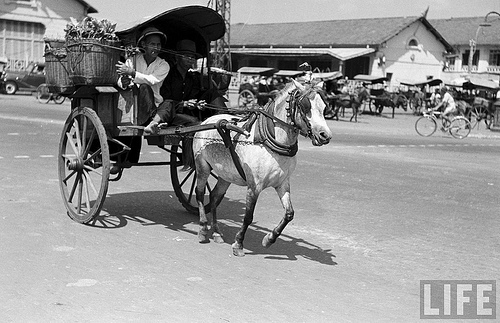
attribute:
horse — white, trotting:
[177, 77, 330, 250]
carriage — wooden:
[56, 0, 229, 224]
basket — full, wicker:
[35, 24, 126, 86]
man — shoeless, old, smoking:
[113, 21, 178, 141]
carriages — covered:
[0, 1, 500, 130]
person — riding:
[414, 82, 474, 141]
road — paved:
[7, 94, 497, 321]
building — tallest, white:
[0, 0, 101, 78]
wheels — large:
[61, 111, 227, 227]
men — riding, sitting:
[126, 25, 206, 134]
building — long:
[208, 21, 451, 89]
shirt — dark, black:
[168, 68, 209, 98]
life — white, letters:
[416, 272, 500, 322]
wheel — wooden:
[166, 114, 235, 214]